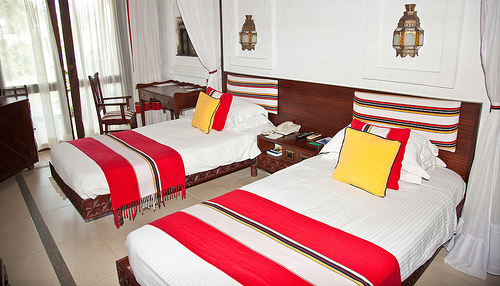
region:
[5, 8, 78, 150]
white curtains on windows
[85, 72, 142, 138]
brown wooden desk chair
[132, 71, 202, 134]
brown wooden office desk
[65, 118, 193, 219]
red white and black blanket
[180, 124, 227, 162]
white bedspread on bed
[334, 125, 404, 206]
yellow throw pillow on bed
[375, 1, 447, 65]
light fixture on wall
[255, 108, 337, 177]
brown wooden bedside table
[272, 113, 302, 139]
white telephone on bedside table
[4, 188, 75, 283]
white and grey linoleum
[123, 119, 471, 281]
a twin sized bed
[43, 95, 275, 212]
a twin sized bed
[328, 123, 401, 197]
a yellow bed pillow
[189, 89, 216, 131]
a yellow bed pillow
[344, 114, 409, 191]
a red white and black bed pillow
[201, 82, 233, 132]
a red white and black bed pillow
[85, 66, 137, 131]
a wooden desk chair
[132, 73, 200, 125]
a small wooden desk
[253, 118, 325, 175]
a wooden bedside table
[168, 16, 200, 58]
a framed wall print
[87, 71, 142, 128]
Wooden chair in front of desk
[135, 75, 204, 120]
Wooden desk next to bed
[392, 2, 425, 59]
Lamp above bed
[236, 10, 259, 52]
Lamp above bed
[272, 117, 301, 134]
White telephone next to bed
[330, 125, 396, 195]
Yellow pillow on top of bed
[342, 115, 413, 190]
Red pillow behind yellow pillow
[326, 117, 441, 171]
White pillow stacked on top of another white pillow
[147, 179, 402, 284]
Red and white blanket with purple and yellow on bed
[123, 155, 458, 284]
White striped sheet on bed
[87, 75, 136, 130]
a brown chair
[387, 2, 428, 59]
a brown wall lamp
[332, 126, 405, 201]
a yellow decorative pillow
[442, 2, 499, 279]
a long white curtain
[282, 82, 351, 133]
part of a brown headboard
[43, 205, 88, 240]
a piece of white floor tile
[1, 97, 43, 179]
part of a brown dresser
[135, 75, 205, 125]
part of a brown desk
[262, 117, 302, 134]
a beige telephone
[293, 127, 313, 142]
a black remote control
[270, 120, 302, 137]
A white telephone.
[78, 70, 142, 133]
A wooden chair at desk.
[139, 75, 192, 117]
A brown wooden desk.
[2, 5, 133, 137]
Curtains covering windows.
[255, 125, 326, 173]
A nightstand between beds.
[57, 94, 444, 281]
Two twin beds.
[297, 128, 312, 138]
A black remote on table.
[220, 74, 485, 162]
A long wooden headboard.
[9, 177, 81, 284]
Gray stripe on tile.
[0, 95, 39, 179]
A wooden cabinet by doors.